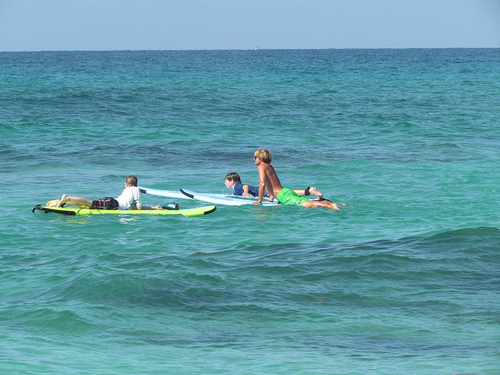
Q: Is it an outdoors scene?
A: Yes, it is outdoors.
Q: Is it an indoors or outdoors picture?
A: It is outdoors.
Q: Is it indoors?
A: No, it is outdoors.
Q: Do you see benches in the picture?
A: No, there are no benches.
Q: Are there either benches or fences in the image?
A: No, there are no benches or fences.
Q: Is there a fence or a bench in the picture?
A: No, there are no benches or fences.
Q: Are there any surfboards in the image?
A: Yes, there is a surfboard.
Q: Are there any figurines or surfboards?
A: Yes, there is a surfboard.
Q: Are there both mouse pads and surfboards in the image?
A: No, there is a surfboard but no mouse pads.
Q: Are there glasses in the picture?
A: No, there are no glasses.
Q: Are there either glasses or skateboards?
A: No, there are no glasses or skateboards.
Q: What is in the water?
A: The surfboard is in the water.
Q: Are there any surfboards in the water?
A: Yes, there is a surfboard in the water.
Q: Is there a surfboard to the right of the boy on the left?
A: Yes, there is a surfboard to the right of the boy.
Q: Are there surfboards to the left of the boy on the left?
A: No, the surfboard is to the right of the boy.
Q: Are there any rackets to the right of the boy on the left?
A: No, there is a surfboard to the right of the boy.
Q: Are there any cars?
A: No, there are no cars.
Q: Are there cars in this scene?
A: No, there are no cars.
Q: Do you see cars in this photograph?
A: No, there are no cars.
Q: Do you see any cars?
A: No, there are no cars.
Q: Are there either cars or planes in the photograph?
A: No, there are no cars or planes.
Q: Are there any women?
A: No, there are no women.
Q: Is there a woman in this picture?
A: No, there are no women.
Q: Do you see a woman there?
A: No, there are no women.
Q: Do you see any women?
A: No, there are no women.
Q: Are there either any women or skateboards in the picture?
A: No, there are no women or skateboards.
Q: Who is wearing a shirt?
A: The boy is wearing a shirt.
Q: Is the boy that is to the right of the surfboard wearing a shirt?
A: Yes, the boy is wearing a shirt.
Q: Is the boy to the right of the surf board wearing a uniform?
A: No, the boy is wearing a shirt.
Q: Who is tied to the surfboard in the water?
A: The boy is tied to the surfboard.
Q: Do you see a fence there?
A: No, there are no fences.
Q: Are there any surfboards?
A: Yes, there is a surfboard.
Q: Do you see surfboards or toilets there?
A: Yes, there is a surfboard.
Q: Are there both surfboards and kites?
A: No, there is a surfboard but no kites.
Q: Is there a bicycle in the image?
A: No, there are no bicycles.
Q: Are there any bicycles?
A: No, there are no bicycles.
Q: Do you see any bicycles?
A: No, there are no bicycles.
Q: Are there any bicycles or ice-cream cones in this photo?
A: No, there are no bicycles or ice-cream cones.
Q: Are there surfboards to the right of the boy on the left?
A: Yes, there is a surfboard to the right of the boy.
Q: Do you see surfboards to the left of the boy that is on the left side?
A: No, the surfboard is to the right of the boy.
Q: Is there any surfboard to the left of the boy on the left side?
A: No, the surfboard is to the right of the boy.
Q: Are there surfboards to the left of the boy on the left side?
A: No, the surfboard is to the right of the boy.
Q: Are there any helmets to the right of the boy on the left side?
A: No, there is a surfboard to the right of the boy.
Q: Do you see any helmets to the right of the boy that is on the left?
A: No, there is a surfboard to the right of the boy.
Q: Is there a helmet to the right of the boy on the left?
A: No, there is a surfboard to the right of the boy.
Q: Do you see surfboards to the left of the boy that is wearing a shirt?
A: Yes, there is a surfboard to the left of the boy.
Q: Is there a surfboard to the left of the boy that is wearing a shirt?
A: Yes, there is a surfboard to the left of the boy.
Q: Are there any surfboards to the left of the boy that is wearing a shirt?
A: Yes, there is a surfboard to the left of the boy.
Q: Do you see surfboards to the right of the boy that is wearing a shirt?
A: No, the surfboard is to the left of the boy.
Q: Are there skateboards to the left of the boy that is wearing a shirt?
A: No, there is a surfboard to the left of the boy.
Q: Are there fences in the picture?
A: No, there are no fences.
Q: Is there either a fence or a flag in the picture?
A: No, there are no fences or flags.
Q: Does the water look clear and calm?
A: No, the water is clear but choppy.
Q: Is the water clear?
A: Yes, the water is clear.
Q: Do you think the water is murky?
A: No, the water is clear.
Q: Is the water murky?
A: No, the water is clear.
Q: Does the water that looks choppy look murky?
A: No, the water is clear.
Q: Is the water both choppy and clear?
A: Yes, the water is choppy and clear.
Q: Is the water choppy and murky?
A: No, the water is choppy but clear.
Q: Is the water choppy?
A: Yes, the water is choppy.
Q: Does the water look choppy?
A: Yes, the water is choppy.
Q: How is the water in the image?
A: The water is choppy.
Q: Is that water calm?
A: No, the water is choppy.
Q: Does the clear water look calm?
A: No, the water is choppy.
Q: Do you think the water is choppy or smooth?
A: The water is choppy.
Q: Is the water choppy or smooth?
A: The water is choppy.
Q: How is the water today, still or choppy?
A: The water is choppy.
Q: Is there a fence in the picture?
A: No, there are no fences.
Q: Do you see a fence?
A: No, there are no fences.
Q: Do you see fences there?
A: No, there are no fences.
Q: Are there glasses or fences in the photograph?
A: No, there are no fences or glasses.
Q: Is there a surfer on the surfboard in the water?
A: No, there is a boy on the surfboard.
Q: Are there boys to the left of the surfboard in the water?
A: Yes, there is a boy to the left of the surf board.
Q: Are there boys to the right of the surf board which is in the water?
A: No, the boy is to the left of the surfboard.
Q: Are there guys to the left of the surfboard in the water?
A: No, there is a boy to the left of the surfboard.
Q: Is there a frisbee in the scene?
A: No, there are no frisbees.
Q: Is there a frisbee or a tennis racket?
A: No, there are no frisbees or rackets.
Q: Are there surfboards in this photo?
A: Yes, there is a surfboard.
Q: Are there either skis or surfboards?
A: Yes, there is a surfboard.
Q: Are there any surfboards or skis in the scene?
A: Yes, there is a surfboard.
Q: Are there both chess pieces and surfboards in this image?
A: No, there is a surfboard but no chess pieces.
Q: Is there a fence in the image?
A: No, there are no fences.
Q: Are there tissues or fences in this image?
A: No, there are no fences or tissues.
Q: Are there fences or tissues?
A: No, there are no fences or tissues.